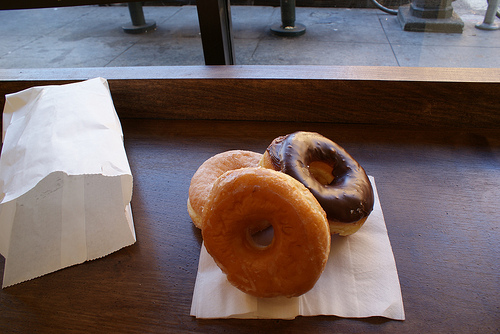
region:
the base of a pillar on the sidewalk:
[398, 0, 465, 32]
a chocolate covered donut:
[262, 130, 374, 237]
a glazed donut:
[202, 165, 330, 299]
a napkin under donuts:
[188, 173, 404, 319]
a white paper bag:
[0, 76, 137, 288]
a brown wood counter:
[0, 66, 499, 332]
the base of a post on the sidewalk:
[269, 0, 306, 35]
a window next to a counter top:
[1, 0, 498, 66]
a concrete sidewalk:
[0, 5, 499, 69]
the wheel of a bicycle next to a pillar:
[372, 0, 416, 13]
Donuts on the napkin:
[190, 135, 362, 291]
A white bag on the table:
[6, 78, 138, 284]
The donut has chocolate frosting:
[288, 138, 361, 210]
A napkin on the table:
[334, 233, 385, 313]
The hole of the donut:
[243, 217, 277, 247]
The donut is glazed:
[205, 178, 325, 296]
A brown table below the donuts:
[418, 161, 480, 329]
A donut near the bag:
[206, 173, 324, 292]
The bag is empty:
[5, 79, 112, 289]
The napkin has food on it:
[332, 238, 381, 303]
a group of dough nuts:
[174, 119, 379, 301]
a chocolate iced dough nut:
[269, 132, 386, 235]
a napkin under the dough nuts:
[178, 137, 451, 325]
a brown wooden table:
[392, 52, 486, 304]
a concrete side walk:
[317, 23, 449, 68]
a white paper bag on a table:
[7, 79, 170, 306]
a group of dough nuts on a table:
[137, 126, 434, 331]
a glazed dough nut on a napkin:
[196, 168, 332, 294]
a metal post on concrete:
[269, 1, 321, 44]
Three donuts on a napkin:
[173, 130, 359, 301]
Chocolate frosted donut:
[257, 110, 354, 205]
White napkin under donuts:
[328, 218, 385, 320]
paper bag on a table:
[26, 90, 98, 242]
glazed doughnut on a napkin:
[229, 193, 316, 279]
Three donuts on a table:
[218, 125, 374, 260]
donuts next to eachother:
[191, 160, 347, 289]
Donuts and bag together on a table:
[66, 110, 414, 309]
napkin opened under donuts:
[194, 270, 402, 326]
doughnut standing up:
[215, 158, 306, 283]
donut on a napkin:
[192, 160, 333, 312]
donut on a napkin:
[177, 141, 267, 228]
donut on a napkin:
[259, 128, 378, 240]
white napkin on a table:
[184, 174, 404, 332]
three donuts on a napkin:
[180, 125, 410, 328]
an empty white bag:
[0, 60, 152, 310]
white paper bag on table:
[0, 60, 141, 308]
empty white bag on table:
[0, 70, 160, 312]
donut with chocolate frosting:
[260, 125, 395, 244]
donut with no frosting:
[180, 160, 345, 319]